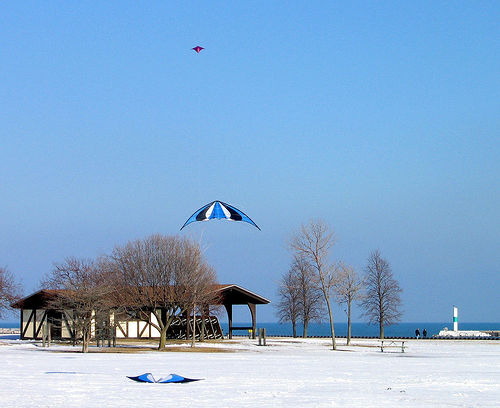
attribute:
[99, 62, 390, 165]
sky — blue, clear, bright, close, clean, light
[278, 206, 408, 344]
tree — bare, thin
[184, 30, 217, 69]
kite — blue, red, flying, high, soaring, small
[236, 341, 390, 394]
ground — white, close, solid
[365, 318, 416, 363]
table — brown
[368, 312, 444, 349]
people — standing